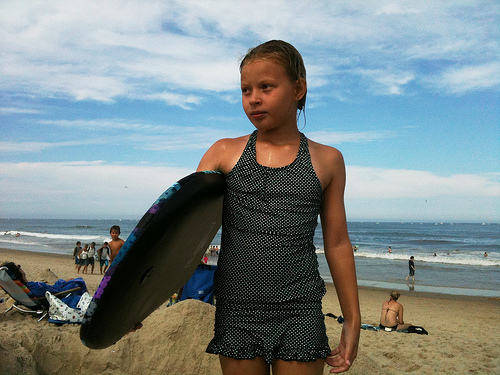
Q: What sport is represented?
A: Boogie boarding.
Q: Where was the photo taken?
A: Beach.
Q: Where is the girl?
A: On sand.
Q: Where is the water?
A: Behind girl.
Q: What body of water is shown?
A: Ocean.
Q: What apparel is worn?
A: Swimming.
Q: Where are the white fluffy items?
A: Sky.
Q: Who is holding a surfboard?
A: A girl.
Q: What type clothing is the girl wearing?
A: A black bathing suit.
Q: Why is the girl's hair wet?
A: From surfing.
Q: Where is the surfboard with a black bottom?
A: Under the girl's arm.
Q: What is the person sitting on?
A: A chair.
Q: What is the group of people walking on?
A: Sand.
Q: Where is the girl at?
A: At the beach.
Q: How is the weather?
A: Sunny.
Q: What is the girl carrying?
A: A surfboard.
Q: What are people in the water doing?
A: Swimming.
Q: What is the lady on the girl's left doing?
A: Tanning.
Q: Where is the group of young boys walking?
A: Along the shore.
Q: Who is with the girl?
A: The girl is by herself.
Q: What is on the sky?
A: Some white clouds.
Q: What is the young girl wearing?
A: A swimming suit.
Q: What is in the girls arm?
A: A surfboard.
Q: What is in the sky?
A: White fluffy clouds.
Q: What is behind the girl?
A: A beach and water.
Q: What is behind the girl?
A: Sand and water.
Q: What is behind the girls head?
A: A blue sky with clouds.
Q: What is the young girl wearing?
A: A black and white swimsuit.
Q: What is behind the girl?
A: Sand.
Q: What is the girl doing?
A: Standing and looking.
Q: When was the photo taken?
A: Daytime.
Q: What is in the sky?
A: Clouds.